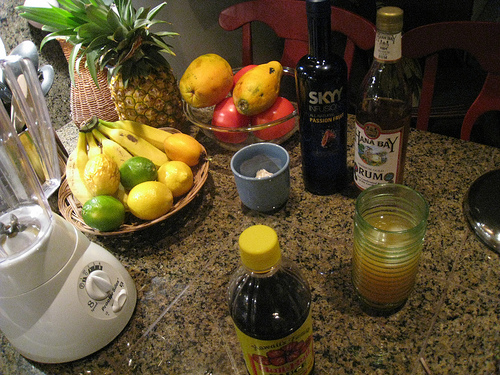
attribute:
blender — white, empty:
[2, 206, 139, 371]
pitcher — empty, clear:
[0, 43, 64, 277]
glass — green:
[355, 181, 428, 318]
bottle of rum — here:
[353, 6, 411, 203]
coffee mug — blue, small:
[231, 141, 292, 212]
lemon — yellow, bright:
[126, 180, 176, 221]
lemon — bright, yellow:
[159, 161, 194, 199]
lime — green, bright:
[82, 196, 126, 233]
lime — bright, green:
[119, 156, 158, 193]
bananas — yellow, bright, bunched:
[66, 116, 180, 206]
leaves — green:
[83, 7, 179, 85]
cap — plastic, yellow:
[375, 7, 406, 33]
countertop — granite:
[2, 3, 498, 372]